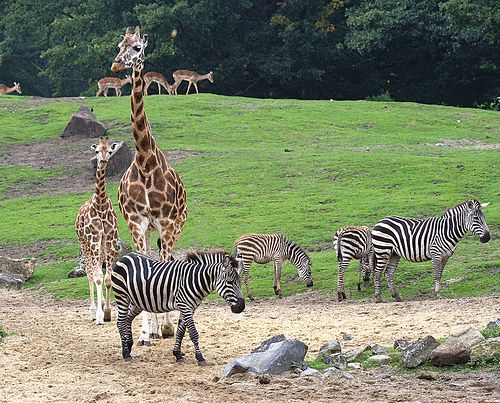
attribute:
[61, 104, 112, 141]
rock — large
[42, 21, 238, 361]
giraffe — walking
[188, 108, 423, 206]
grass — pretty, green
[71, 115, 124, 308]
giraffe — walking